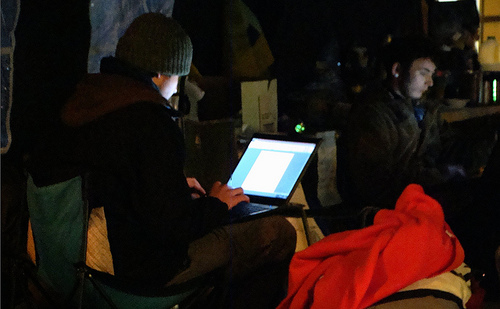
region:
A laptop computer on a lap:
[191, 130, 326, 233]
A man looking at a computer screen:
[352, 41, 482, 185]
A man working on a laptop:
[42, 27, 314, 307]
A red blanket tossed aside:
[278, 184, 477, 306]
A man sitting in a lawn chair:
[17, 0, 257, 308]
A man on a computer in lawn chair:
[20, 14, 320, 295]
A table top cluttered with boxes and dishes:
[196, 10, 496, 165]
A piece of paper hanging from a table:
[313, 130, 346, 212]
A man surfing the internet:
[58, 8, 325, 295]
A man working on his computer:
[342, 38, 499, 195]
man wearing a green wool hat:
[116, 8, 193, 75]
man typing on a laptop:
[187, 135, 322, 225]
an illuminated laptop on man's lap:
[172, 133, 318, 289]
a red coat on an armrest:
[272, 184, 464, 306]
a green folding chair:
[23, 170, 211, 307]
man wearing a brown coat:
[338, 83, 450, 195]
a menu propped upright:
[239, 78, 279, 135]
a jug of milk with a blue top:
[476, 33, 499, 69]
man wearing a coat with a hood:
[52, 69, 229, 271]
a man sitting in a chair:
[335, 41, 497, 306]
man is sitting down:
[44, 10, 319, 274]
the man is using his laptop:
[191, 100, 317, 240]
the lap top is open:
[181, 102, 324, 238]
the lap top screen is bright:
[214, 118, 327, 218]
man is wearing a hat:
[88, 0, 214, 102]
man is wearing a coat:
[20, 67, 257, 264]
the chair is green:
[5, 150, 120, 305]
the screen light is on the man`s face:
[125, 56, 207, 105]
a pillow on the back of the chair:
[2, 167, 119, 287]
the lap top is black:
[213, 112, 323, 229]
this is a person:
[27, 15, 280, 305]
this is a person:
[344, 43, 453, 228]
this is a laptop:
[184, 129, 330, 237]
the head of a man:
[119, 12, 212, 114]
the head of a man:
[392, 29, 447, 111]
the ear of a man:
[382, 58, 407, 83]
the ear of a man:
[147, 63, 170, 83]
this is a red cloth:
[293, 174, 484, 307]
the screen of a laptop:
[230, 125, 307, 200]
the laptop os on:
[221, 125, 324, 205]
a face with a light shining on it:
[153, 63, 185, 105]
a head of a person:
[389, 33, 439, 102]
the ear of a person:
[388, 57, 404, 80]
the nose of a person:
[424, 77, 436, 90]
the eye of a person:
[419, 65, 432, 82]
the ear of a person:
[149, 66, 167, 83]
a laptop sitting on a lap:
[211, 133, 312, 225]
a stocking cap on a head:
[116, 8, 197, 80]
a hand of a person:
[209, 177, 250, 206]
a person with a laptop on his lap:
[96, 9, 313, 296]